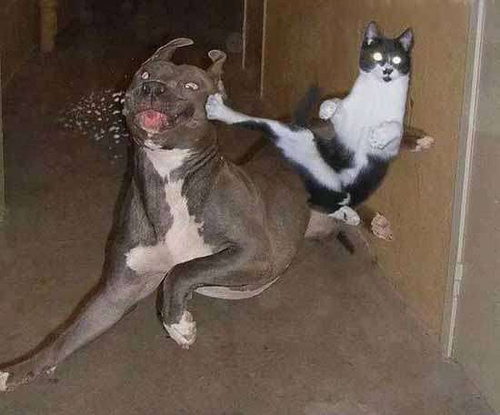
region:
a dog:
[43, 135, 333, 367]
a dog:
[110, 179, 230, 353]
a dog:
[179, 199, 268, 341]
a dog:
[119, 96, 236, 269]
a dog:
[159, 96, 324, 386]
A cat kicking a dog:
[31, 33, 450, 376]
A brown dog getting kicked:
[73, 49, 318, 369]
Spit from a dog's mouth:
[67, 83, 129, 153]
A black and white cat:
[230, 28, 443, 237]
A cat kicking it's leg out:
[236, 20, 451, 255]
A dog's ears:
[116, 19, 243, 81]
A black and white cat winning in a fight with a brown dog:
[50, 11, 497, 401]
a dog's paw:
[146, 295, 221, 359]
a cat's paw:
[317, 191, 363, 232]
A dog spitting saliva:
[56, 36, 253, 176]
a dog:
[156, 161, 263, 241]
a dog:
[144, 121, 267, 293]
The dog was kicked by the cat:
[79, 42, 296, 316]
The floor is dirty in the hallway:
[287, 325, 362, 412]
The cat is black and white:
[240, 21, 432, 236]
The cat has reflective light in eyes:
[361, 38, 419, 75]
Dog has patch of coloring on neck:
[130, 147, 258, 290]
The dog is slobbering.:
[79, 74, 169, 169]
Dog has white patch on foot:
[145, 289, 238, 374]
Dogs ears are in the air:
[145, 40, 252, 88]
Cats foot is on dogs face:
[184, 68, 359, 178]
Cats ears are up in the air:
[356, 14, 435, 54]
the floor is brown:
[275, 322, 353, 399]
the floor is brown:
[282, 297, 352, 412]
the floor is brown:
[309, 353, 381, 410]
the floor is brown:
[294, 302, 350, 404]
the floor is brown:
[318, 308, 355, 398]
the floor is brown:
[304, 305, 343, 410]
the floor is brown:
[290, 301, 369, 412]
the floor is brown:
[343, 323, 369, 399]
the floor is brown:
[303, 320, 360, 410]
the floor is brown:
[242, 257, 342, 408]